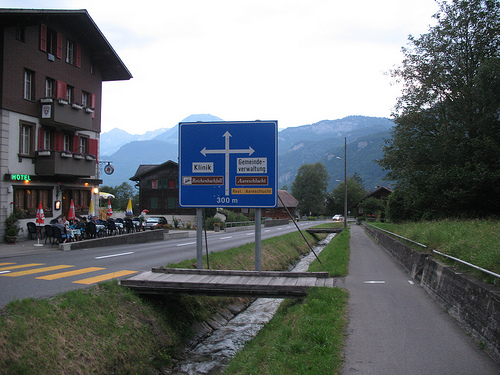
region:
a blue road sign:
[166, 115, 281, 213]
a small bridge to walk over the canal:
[139, 254, 345, 316]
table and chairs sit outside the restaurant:
[29, 195, 169, 243]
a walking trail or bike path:
[346, 224, 472, 373]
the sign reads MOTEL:
[3, 170, 44, 185]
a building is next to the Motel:
[128, 158, 216, 228]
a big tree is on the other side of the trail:
[383, 13, 498, 214]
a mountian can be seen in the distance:
[111, 116, 414, 196]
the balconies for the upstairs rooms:
[32, 91, 99, 181]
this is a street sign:
[158, 99, 315, 294]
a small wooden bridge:
[119, 252, 341, 309]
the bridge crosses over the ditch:
[109, 265, 336, 310]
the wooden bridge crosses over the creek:
[101, 246, 354, 311]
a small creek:
[157, 239, 323, 374]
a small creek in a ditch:
[158, 214, 355, 372]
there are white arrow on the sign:
[200, 118, 284, 207]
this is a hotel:
[3, 1, 132, 267]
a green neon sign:
[3, 164, 43, 186]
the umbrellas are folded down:
[27, 185, 148, 252]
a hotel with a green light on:
[1, 1, 169, 263]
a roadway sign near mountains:
[149, 103, 288, 293]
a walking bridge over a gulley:
[28, 210, 357, 372]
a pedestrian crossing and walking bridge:
[4, 227, 457, 348]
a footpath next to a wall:
[328, 202, 498, 374]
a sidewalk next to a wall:
[342, 188, 498, 374]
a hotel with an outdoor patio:
[7, 153, 177, 258]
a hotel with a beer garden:
[5, 160, 175, 265]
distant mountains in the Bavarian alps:
[80, 92, 430, 265]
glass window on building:
[46, 28, 56, 55]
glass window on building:
[65, 37, 74, 66]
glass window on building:
[14, 24, 24, 39]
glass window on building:
[81, 89, 91, 109]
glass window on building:
[63, 80, 73, 102]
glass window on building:
[43, 74, 53, 97]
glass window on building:
[23, 69, 33, 99]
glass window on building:
[21, 123, 30, 152]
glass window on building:
[44, 133, 52, 149]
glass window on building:
[63, 135, 70, 153]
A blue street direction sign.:
[174, 117, 280, 212]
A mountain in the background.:
[286, 112, 391, 159]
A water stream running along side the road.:
[182, 224, 319, 374]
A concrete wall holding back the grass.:
[362, 217, 499, 355]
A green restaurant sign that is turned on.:
[7, 168, 32, 183]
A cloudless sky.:
[169, 7, 405, 84]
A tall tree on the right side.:
[378, 13, 498, 225]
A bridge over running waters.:
[119, 264, 341, 295]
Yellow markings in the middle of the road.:
[5, 255, 131, 293]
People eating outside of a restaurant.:
[48, 214, 130, 238]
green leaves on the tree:
[429, 136, 452, 166]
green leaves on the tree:
[459, 71, 485, 118]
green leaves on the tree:
[455, 30, 490, 80]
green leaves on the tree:
[300, 176, 304, 188]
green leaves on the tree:
[340, 173, 365, 200]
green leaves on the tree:
[300, 181, 320, 199]